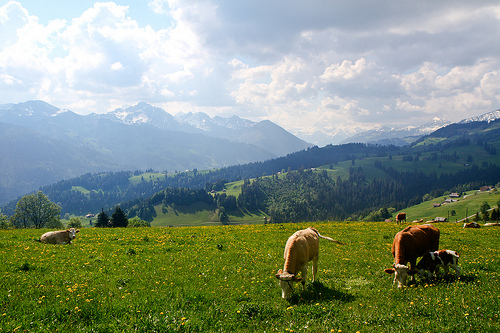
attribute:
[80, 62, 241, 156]
mountain — tall, far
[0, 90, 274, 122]
mountains — group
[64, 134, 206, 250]
hill — green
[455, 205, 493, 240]
can — cream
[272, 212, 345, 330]
cow — eating, laying, looking, brown, small, colored, white, five, sitting, swinging, group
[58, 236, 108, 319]
flower — yellow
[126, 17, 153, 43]
sky — blue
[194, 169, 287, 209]
trees — meadow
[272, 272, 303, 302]
head — white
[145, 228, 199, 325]
grass — green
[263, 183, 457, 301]
cows — group